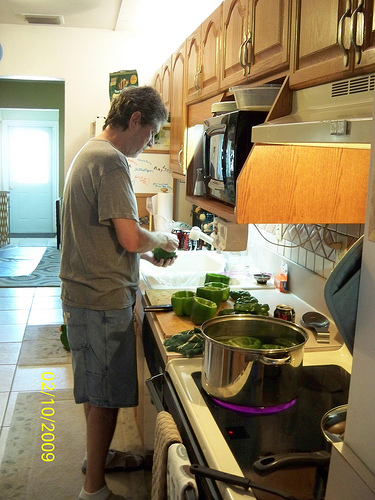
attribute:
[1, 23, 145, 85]
wall — white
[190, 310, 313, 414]
pot — stainless, silver, large, grey, metallic, container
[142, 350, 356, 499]
stove — stock, silver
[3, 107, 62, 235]
door — white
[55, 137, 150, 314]
tee shirt — grey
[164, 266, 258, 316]
peppers — green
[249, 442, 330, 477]
handle — black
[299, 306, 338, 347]
spoon — metal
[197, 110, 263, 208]
microwave — black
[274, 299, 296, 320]
soda — aluminum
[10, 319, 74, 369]
rug — tan colored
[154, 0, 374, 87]
cabinets — wood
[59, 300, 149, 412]
shorts — light blue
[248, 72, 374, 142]
hood — white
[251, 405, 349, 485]
frying pan — black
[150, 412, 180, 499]
towel — brown